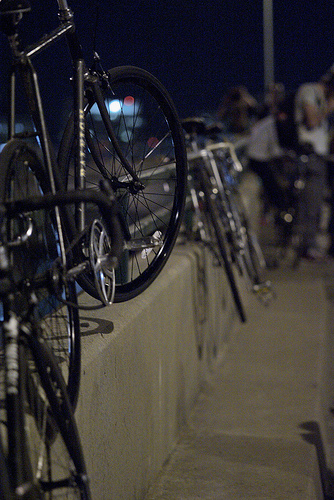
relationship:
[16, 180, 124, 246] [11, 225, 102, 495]
handles on bike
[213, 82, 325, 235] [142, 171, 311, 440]
people hanging out on side of a bridge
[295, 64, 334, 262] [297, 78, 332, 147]
man in a shirt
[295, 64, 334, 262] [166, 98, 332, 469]
man standing on side of bridge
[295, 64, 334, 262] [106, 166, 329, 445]
man resting on bridge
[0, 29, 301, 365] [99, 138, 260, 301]
bicycles on ramp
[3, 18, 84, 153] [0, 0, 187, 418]
frame to bicycles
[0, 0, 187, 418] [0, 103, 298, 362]
bicycles on top of bridge's ramp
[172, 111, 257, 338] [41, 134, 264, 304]
bike on ramp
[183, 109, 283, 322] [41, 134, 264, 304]
bike on ramp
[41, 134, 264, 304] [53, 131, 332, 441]
ramp of bridge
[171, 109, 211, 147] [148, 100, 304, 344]
seat to bike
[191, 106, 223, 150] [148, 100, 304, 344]
seat to bike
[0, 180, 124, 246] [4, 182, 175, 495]
handles to bike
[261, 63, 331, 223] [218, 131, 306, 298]
people standing by wall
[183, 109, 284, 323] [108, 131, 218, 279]
bike fixed to railing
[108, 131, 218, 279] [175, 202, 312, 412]
railing on wall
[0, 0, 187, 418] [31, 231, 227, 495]
bicycles parked on top of wall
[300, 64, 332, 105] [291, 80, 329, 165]
man wearing a shirt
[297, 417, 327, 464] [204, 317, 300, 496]
shadow on ground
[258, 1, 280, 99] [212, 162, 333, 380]
light post along sidewalk